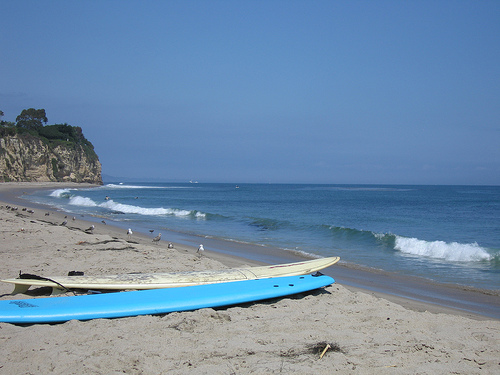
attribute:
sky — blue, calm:
[1, 1, 499, 184]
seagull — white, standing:
[195, 243, 206, 254]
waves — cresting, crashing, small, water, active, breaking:
[384, 235, 495, 265]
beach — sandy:
[2, 2, 499, 373]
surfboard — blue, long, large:
[2, 269, 337, 327]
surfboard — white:
[3, 254, 351, 290]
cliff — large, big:
[0, 106, 105, 188]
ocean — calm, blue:
[5, 180, 499, 287]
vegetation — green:
[2, 108, 87, 146]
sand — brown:
[0, 178, 497, 375]